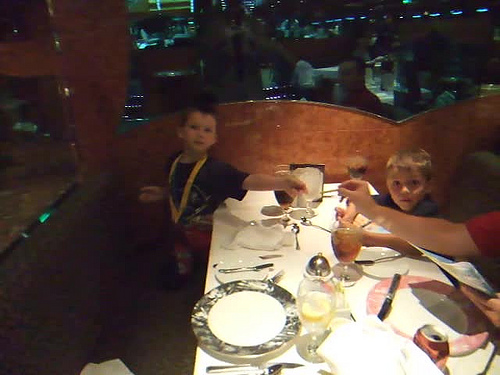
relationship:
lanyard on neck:
[163, 161, 201, 217] [171, 145, 211, 163]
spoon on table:
[303, 210, 333, 234] [198, 172, 495, 371]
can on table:
[413, 324, 450, 373] [198, 172, 495, 371]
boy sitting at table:
[379, 148, 439, 216] [198, 172, 495, 371]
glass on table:
[327, 224, 364, 284] [202, 158, 498, 348]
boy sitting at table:
[163, 100, 242, 236] [198, 172, 495, 371]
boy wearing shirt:
[138, 107, 308, 290] [160, 152, 245, 225]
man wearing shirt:
[332, 51, 378, 113] [341, 88, 392, 111]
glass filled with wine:
[294, 278, 333, 360] [300, 297, 327, 324]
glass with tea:
[331, 227, 363, 264] [332, 237, 357, 262]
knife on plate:
[219, 263, 274, 274] [212, 249, 272, 283]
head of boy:
[174, 104, 215, 152] [138, 107, 308, 290]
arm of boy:
[135, 180, 184, 201] [138, 107, 308, 290]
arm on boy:
[230, 150, 338, 231] [138, 107, 308, 290]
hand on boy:
[279, 173, 301, 199] [138, 107, 308, 290]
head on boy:
[360, 145, 460, 245] [334, 147, 439, 258]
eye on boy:
[385, 166, 435, 196] [334, 147, 439, 258]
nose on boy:
[394, 183, 419, 200] [334, 147, 439, 258]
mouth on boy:
[386, 189, 421, 210] [334, 147, 439, 258]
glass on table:
[331, 227, 363, 264] [180, 155, 493, 369]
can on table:
[413, 324, 450, 373] [180, 155, 493, 369]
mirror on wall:
[0, 0, 83, 277] [8, 0, 201, 362]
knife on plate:
[219, 257, 277, 276] [210, 233, 284, 300]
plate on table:
[181, 273, 314, 360] [190, 139, 499, 368]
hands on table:
[324, 167, 378, 248] [190, 139, 499, 368]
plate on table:
[203, 225, 288, 296] [188, 170, 482, 362]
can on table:
[400, 304, 461, 373] [190, 139, 499, 368]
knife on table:
[377, 273, 401, 321] [188, 170, 482, 362]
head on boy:
[385, 146, 433, 211] [358, 116, 457, 259]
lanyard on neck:
[168, 160, 206, 224] [175, 139, 221, 178]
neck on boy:
[175, 139, 221, 178] [137, 76, 303, 275]